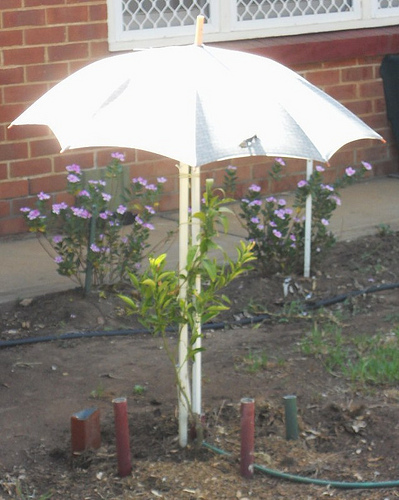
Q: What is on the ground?
A: Umbrella.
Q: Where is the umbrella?
A: On the ground.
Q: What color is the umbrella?
A: White.